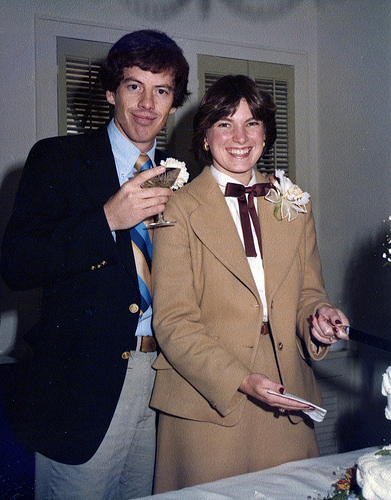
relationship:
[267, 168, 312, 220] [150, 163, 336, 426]
flower on jacket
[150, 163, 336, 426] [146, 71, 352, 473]
jacket of woman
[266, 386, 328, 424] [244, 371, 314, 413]
handkerchief worn in hand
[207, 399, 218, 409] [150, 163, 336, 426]
button on jacket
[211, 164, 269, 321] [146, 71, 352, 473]
shirt on woman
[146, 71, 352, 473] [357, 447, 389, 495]
woman cutting wedding cake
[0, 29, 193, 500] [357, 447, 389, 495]
man cutting wedding cake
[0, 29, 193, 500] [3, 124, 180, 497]
man dressed in a suit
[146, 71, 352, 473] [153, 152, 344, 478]
woman in a dress suit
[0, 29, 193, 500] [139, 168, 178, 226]
man holding champagne glass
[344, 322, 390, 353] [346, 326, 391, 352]
blade of a blade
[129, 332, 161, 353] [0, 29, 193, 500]
belt of a man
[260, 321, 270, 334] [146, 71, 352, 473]
belt of a woman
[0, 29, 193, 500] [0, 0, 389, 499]
man posing for photo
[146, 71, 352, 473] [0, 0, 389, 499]
woman posing for photo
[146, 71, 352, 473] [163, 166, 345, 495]
woman wearing a suit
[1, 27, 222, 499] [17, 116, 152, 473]
man wearing a blazer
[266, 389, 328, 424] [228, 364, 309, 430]
handkerchief in a hand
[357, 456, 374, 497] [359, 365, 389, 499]
edge of a white cake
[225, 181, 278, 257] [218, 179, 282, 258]
bow tied in a bow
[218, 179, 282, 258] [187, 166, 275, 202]
bow at a collar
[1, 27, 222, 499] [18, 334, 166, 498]
man has slacks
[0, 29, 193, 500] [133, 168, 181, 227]
man holding champagne glass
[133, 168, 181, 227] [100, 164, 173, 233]
champagne glass in h hand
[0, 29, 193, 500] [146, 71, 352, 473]
man standing behind woman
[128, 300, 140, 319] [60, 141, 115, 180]
button on jacket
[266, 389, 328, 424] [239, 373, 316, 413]
handkerchief in hand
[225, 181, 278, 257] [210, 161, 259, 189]
bow around neck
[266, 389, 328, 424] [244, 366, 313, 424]
handkerchief in hand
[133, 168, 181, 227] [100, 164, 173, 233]
champagne glass in hand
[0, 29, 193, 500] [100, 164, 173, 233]
man has hand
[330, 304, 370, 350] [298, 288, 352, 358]
fork in hand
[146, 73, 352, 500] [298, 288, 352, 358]
woman has hand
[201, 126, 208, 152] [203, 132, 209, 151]
ear has ear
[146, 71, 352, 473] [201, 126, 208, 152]
woman has ear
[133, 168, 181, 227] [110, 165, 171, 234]
champagne glass in hand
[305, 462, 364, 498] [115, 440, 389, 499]
flowers on table